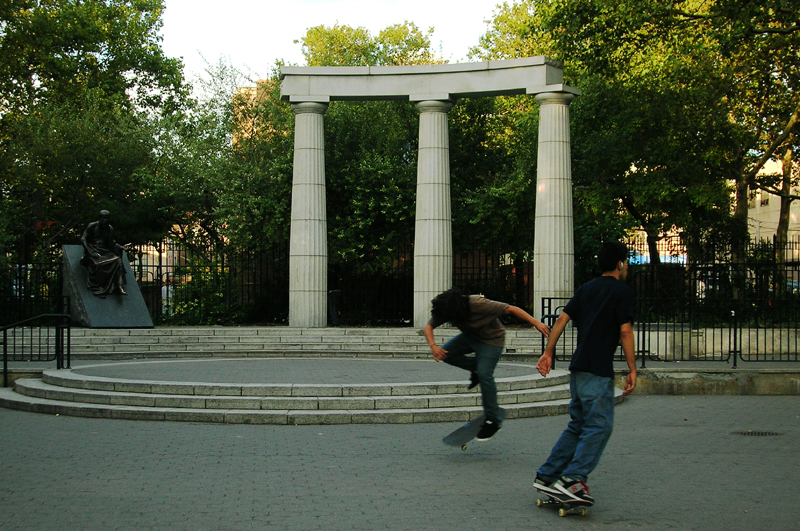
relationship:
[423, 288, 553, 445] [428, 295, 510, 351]
skater wearing shirt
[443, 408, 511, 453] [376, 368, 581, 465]
skateboard in air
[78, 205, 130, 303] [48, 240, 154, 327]
statue on side of monument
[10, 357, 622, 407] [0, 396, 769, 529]
steps on concrete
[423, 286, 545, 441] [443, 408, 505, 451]
boy on skateboard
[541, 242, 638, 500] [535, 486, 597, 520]
boy on skateboard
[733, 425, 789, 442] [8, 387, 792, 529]
hole on ground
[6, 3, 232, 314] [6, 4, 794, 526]
tree in city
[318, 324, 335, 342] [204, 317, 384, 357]
brick in the wall